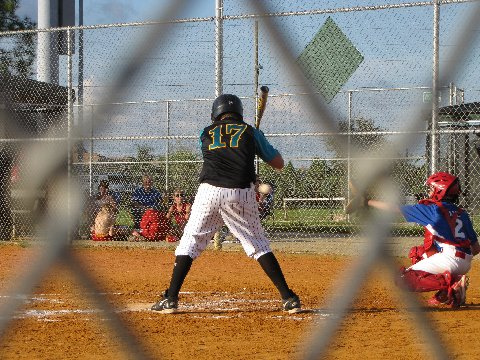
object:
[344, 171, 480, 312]
catcher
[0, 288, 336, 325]
chalk outlines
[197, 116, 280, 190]
shirt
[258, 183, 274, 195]
baseball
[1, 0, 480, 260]
fence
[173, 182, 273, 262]
pants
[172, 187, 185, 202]
head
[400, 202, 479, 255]
jersey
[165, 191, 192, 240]
person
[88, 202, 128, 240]
person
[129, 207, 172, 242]
person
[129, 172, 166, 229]
person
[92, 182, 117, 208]
person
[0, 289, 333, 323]
white line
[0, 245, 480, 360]
dirt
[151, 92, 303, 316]
batter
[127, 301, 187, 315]
home plate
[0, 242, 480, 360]
ground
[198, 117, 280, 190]
jersey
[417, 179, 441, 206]
mask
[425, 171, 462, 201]
helmet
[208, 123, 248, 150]
number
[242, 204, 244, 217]
stripe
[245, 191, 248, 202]
stripe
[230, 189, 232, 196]
stripe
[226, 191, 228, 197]
stripe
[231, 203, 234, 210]
stripe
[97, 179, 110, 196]
head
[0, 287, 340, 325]
batters box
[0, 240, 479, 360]
field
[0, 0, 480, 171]
air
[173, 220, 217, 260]
stripes